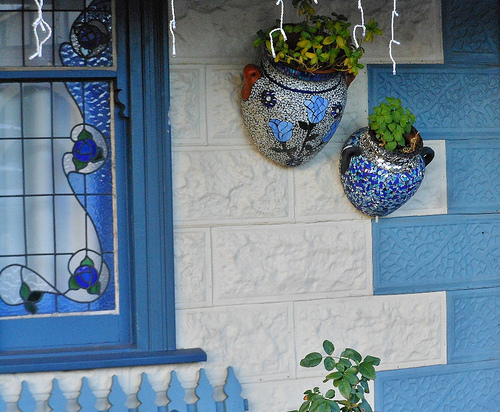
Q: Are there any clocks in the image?
A: No, there are no clocks.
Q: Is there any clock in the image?
A: No, there are no clocks.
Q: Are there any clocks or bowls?
A: No, there are no clocks or bowls.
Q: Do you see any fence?
A: Yes, there is a fence.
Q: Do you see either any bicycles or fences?
A: Yes, there is a fence.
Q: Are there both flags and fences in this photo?
A: No, there is a fence but no flags.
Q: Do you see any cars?
A: No, there are no cars.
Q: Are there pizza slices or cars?
A: No, there are no cars or pizza slices.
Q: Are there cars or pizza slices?
A: No, there are no cars or pizza slices.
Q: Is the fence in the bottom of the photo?
A: Yes, the fence is in the bottom of the image.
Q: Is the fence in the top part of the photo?
A: No, the fence is in the bottom of the image.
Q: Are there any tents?
A: No, there are no tents.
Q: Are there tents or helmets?
A: No, there are no tents or helmets.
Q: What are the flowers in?
A: The flowers are in the vase.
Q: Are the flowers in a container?
A: No, the flowers are in a vase.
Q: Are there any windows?
A: Yes, there is a window.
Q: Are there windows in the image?
A: Yes, there is a window.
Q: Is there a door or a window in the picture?
A: Yes, there is a window.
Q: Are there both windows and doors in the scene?
A: No, there is a window but no doors.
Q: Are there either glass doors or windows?
A: Yes, there is a glass window.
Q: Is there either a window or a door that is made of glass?
A: Yes, the window is made of glass.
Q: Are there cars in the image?
A: No, there are no cars.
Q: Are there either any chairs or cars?
A: No, there are no cars or chairs.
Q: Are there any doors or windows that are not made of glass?
A: No, there is a window but it is made of glass.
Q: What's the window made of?
A: The window is made of glass.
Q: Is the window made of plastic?
A: No, the window is made of glass.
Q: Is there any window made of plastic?
A: No, there is a window but it is made of glass.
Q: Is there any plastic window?
A: No, there is a window but it is made of glass.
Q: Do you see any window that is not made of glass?
A: No, there is a window but it is made of glass.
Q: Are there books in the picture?
A: No, there are no books.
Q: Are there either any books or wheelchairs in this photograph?
A: No, there are no books or wheelchairs.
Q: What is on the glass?
A: The rose is on the glass.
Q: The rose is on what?
A: The rose is on the glass.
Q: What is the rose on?
A: The rose is on the glass.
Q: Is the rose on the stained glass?
A: Yes, the rose is on the glass.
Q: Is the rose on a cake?
A: No, the rose is on the glass.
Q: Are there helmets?
A: No, there are no helmets.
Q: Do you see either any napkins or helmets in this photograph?
A: No, there are no helmets or napkins.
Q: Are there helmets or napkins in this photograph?
A: No, there are no helmets or napkins.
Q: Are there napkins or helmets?
A: No, there are no helmets or napkins.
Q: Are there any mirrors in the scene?
A: No, there are no mirrors.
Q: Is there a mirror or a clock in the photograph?
A: No, there are no mirrors or clocks.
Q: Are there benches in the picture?
A: No, there are no benches.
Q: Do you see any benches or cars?
A: No, there are no benches or cars.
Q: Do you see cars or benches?
A: No, there are no benches or cars.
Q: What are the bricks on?
A: The bricks are on the wall.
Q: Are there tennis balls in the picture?
A: No, there are no tennis balls.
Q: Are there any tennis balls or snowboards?
A: No, there are no tennis balls or snowboards.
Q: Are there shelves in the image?
A: No, there are no shelves.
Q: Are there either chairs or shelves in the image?
A: No, there are no shelves or chairs.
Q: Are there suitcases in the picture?
A: No, there are no suitcases.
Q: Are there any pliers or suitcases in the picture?
A: No, there are no suitcases or pliers.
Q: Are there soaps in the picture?
A: No, there are no soaps.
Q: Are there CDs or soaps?
A: No, there are no soaps or cds.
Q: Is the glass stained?
A: Yes, the glass is stained.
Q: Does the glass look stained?
A: Yes, the glass is stained.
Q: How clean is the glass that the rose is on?
A: The glass is stained.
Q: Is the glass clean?
A: No, the glass is stained.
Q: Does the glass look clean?
A: No, the glass is stained.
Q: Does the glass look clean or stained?
A: The glass is stained.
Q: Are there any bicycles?
A: No, there are no bicycles.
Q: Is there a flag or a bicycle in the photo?
A: No, there are no bicycles or flags.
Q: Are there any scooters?
A: No, there are no scooters.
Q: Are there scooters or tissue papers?
A: No, there are no scooters or tissue papers.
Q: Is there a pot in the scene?
A: Yes, there is a pot.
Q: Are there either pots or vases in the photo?
A: Yes, there is a pot.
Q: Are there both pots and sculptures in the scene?
A: No, there is a pot but no sculptures.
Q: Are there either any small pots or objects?
A: Yes, there is a small pot.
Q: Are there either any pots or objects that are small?
A: Yes, the pot is small.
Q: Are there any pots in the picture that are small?
A: Yes, there is a small pot.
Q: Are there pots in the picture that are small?
A: Yes, there is a pot that is small.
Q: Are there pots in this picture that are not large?
A: Yes, there is a small pot.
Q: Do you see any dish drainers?
A: No, there are no dish drainers.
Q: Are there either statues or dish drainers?
A: No, there are no dish drainers or statues.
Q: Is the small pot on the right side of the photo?
A: Yes, the pot is on the right of the image.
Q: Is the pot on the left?
A: No, the pot is on the right of the image.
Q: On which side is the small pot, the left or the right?
A: The pot is on the right of the image.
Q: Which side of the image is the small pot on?
A: The pot is on the right of the image.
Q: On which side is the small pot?
A: The pot is on the right of the image.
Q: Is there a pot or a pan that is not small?
A: No, there is a pot but it is small.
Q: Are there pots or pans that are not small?
A: No, there is a pot but it is small.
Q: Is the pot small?
A: Yes, the pot is small.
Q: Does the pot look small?
A: Yes, the pot is small.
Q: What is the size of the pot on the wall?
A: The pot is small.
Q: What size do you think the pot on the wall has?
A: The pot has small size.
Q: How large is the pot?
A: The pot is small.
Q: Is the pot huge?
A: No, the pot is small.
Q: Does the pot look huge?
A: No, the pot is small.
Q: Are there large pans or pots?
A: No, there is a pot but it is small.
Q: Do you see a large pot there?
A: No, there is a pot but it is small.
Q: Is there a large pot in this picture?
A: No, there is a pot but it is small.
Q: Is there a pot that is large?
A: No, there is a pot but it is small.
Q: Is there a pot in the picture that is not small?
A: No, there is a pot but it is small.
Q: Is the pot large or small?
A: The pot is small.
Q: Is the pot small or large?
A: The pot is small.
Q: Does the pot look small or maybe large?
A: The pot is small.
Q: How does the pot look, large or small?
A: The pot is small.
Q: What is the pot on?
A: The pot is on the wall.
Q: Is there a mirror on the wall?
A: No, there is a pot on the wall.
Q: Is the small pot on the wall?
A: Yes, the pot is on the wall.